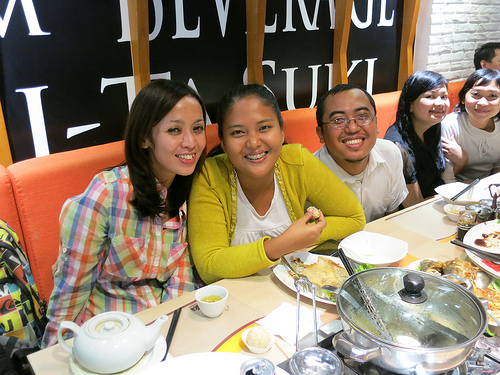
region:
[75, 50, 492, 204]
the people are smiling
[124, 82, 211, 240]
the woman has long hair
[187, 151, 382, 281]
the woman's sweater is yellow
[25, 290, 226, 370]
a tea kettle is on the table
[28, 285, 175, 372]
the tea kettle is white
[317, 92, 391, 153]
the man is wearing glasses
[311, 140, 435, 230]
the man's shirt is white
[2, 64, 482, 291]
the seating is orange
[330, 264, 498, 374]
a pot is on the table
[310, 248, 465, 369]
the pot is silver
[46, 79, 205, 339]
A young woman in a colorful checkered shirt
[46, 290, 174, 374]
A white teapot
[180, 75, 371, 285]
A young woman wearing a yellow sweater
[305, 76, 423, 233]
A young man wearing glasses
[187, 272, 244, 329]
A small cup of soup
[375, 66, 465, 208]
A young woman wearing a blue shirt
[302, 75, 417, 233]
A young man wearing a white shirt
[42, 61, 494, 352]
A group of 5 people eating together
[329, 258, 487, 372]
A covered silver serving dish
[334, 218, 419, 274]
a white empty plate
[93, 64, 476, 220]
these are some people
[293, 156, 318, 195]
this is a sweater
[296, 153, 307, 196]
the sweater is yellow in color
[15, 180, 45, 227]
this is a seat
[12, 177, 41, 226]
the seat is orange in color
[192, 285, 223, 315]
this is a bowl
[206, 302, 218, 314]
the bowl is white in color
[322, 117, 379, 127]
this is a pair of spectacles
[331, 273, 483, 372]
this is a serving dish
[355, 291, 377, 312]
the lid is made of glass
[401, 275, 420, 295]
part of a bolt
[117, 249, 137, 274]
part of a pocket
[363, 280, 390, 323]
part of a lid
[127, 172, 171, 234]
hair of a lady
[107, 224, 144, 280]
part of a shirt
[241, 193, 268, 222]
part of a collar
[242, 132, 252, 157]
nose of the lady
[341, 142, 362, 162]
part of a chin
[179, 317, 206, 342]
part of a table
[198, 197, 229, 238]
part of a sweater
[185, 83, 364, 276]
girl in lime green sweater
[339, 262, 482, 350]
condensation on inside of pot lid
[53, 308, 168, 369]
small white porcelain teapot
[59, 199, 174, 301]
plaid button down shirt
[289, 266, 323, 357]
stainless steel tongs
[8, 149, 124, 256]
orange leather wall bench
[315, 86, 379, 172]
eyeglasses on man's face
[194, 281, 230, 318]
white cup of yellow broth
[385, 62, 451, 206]
girl wit long black hair smiling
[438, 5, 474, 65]
white painted brick on wall